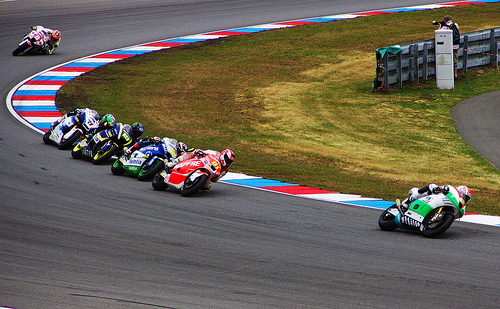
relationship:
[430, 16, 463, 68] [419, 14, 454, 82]
man taking picture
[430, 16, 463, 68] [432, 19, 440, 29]
man holding camera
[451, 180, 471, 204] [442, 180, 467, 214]
man on green bike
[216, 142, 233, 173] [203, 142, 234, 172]
man on red bike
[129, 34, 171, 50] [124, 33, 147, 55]
white and blue lines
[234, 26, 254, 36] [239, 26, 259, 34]
blue lines on road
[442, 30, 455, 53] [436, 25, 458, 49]
man in pink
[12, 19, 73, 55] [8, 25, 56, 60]
man in back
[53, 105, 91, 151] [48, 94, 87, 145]
fifth bike racing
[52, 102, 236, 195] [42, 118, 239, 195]
four motorcycles racing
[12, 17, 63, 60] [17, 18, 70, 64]
motorcycle left behind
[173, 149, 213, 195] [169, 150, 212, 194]
motorbike on track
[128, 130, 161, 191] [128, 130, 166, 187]
middle motorbike racing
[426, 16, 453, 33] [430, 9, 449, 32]
man taking video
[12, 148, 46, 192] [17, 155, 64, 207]
spots on road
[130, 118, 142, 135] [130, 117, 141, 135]
man in helmet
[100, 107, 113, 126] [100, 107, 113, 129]
man in green helmet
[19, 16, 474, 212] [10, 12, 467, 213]
seven bikes racing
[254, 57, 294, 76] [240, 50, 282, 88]
middle burnt grass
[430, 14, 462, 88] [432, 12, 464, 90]
man with camera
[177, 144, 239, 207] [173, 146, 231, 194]
red motorbike driving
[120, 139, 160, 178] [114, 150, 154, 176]
lime green bike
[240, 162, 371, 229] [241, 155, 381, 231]
space between first bike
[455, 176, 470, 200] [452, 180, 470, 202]
head bike helmet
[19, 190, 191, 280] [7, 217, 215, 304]
black tire marks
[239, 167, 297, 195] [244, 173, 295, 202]
painted design on track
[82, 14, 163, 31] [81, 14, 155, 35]
empty street pavement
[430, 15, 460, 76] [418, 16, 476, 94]
man standing on sideline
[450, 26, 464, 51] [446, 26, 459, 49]
man wearing bag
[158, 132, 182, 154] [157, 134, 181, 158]
green bike driver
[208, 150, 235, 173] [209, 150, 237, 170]
red bike driver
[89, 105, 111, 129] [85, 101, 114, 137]
driver with green helmet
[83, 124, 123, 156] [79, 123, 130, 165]
blue and yellow bike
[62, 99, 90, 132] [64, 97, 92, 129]
blue and white bike driver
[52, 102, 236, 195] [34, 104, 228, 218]
four bikes together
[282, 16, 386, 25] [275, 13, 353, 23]
red white and blue stripes lines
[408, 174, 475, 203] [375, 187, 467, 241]
motorcyclist rides motorcycle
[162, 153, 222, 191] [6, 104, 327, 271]
motorbike on road race